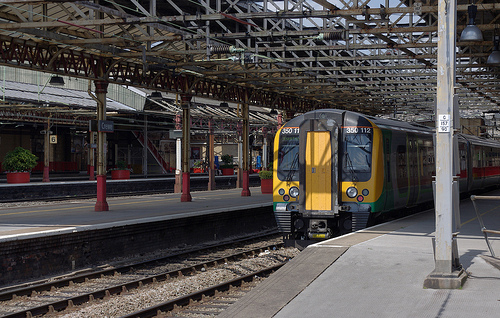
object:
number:
[345, 126, 351, 133]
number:
[285, 125, 290, 134]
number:
[290, 127, 295, 135]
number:
[292, 126, 299, 134]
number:
[365, 126, 372, 133]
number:
[345, 124, 375, 135]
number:
[344, 126, 359, 133]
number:
[359, 126, 373, 133]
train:
[270, 102, 498, 244]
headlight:
[345, 185, 357, 198]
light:
[355, 194, 366, 203]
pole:
[429, 0, 462, 274]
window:
[277, 131, 301, 180]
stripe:
[278, 124, 377, 133]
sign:
[50, 134, 60, 144]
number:
[49, 135, 57, 141]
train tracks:
[0, 229, 301, 318]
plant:
[260, 166, 273, 195]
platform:
[0, 178, 275, 279]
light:
[48, 72, 65, 87]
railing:
[470, 189, 500, 265]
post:
[91, 69, 111, 212]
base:
[93, 172, 110, 212]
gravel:
[0, 243, 291, 318]